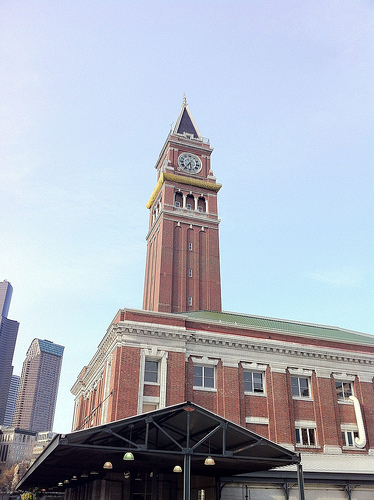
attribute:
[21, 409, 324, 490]
awning — black 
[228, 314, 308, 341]
roof — Green 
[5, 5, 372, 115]
sky — blue 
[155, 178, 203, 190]
divider — yellow, concrete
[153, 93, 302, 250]
tower — clock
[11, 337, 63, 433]
office — tall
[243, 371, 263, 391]
window — slightly opened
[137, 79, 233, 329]
tower — clock, brick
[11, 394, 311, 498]
covered area — outdoor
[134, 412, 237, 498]
pavilion — black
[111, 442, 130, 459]
light — Electrical 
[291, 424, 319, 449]
window — opened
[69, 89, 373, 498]
building — brick, tall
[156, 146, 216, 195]
clock — brick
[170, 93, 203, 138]
steeple — pointed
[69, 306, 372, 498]
building — red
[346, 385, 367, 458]
tube — white 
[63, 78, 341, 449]
building — brick